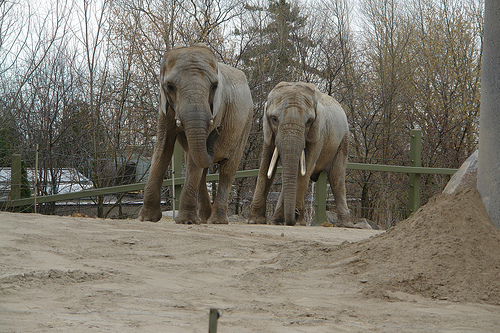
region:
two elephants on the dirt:
[139, 49, 351, 227]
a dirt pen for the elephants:
[2, 211, 492, 330]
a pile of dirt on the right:
[355, 187, 498, 294]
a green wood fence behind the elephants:
[4, 133, 474, 227]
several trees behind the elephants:
[8, 7, 482, 220]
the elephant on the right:
[253, 88, 353, 228]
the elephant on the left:
[137, 49, 252, 224]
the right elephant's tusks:
[267, 148, 305, 180]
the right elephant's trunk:
[277, 126, 297, 224]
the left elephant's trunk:
[185, 119, 213, 169]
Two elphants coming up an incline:
[135, 32, 354, 227]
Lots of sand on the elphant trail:
[6, 219, 494, 329]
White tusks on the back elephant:
[263, 140, 312, 177]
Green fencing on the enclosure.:
[13, 157, 466, 212]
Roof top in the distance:
[0, 169, 98, 196]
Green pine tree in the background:
[246, 2, 316, 82]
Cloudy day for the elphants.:
[6, 7, 488, 67]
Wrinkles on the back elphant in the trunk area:
[280, 96, 301, 212]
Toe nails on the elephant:
[133, 213, 205, 227]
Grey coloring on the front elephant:
[213, 75, 251, 115]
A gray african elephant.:
[242, 80, 354, 228]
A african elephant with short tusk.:
[134, 41, 254, 225]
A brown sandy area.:
[0, 188, 499, 331]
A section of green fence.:
[346, 129, 461, 229]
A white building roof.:
[24, 165, 93, 199]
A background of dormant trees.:
[0, 0, 482, 198]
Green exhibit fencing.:
[0, 153, 146, 211]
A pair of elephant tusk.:
[265, 145, 307, 180]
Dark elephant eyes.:
[268, 115, 315, 127]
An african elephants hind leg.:
[328, 128, 357, 228]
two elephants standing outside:
[143, 41, 355, 232]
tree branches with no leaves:
[1, 0, 115, 89]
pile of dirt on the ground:
[366, 193, 486, 303]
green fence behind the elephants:
[353, 126, 430, 198]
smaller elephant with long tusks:
[255, 83, 355, 235]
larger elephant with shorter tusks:
[141, 39, 255, 221]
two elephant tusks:
[268, 145, 306, 180]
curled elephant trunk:
[183, 116, 223, 169]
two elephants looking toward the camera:
[138, 42, 358, 231]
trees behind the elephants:
[6, 0, 448, 128]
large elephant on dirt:
[141, 59, 232, 256]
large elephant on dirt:
[257, 53, 383, 227]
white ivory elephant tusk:
[263, 146, 289, 194]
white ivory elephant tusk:
[294, 144, 314, 181]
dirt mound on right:
[369, 177, 443, 320]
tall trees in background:
[15, 27, 400, 130]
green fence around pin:
[94, 153, 490, 273]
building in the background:
[3, 145, 104, 206]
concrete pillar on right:
[457, 32, 494, 149]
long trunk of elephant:
[277, 129, 295, 243]